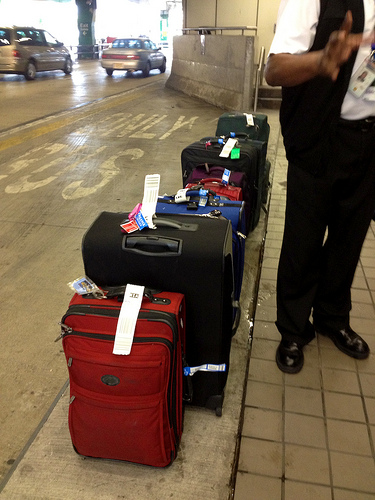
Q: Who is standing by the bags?
A: A man is standing there.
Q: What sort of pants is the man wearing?
A: They are black pants.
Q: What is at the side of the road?
A: Many pieces of luggage.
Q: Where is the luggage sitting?
A: The luggage is on the sidewalk.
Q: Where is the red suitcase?
A: It is on the sidewalk.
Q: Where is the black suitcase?
A: It on the sidewalk behind the red one.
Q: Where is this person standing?
A: He is in the foreground.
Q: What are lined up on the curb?
A: Luggage.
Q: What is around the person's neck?
A: Lanyard with ID.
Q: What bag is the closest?
A: Red bag.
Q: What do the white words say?
A: Only bus.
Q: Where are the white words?
A: On the pavement.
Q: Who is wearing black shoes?
A: A person.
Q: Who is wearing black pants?
A: A person.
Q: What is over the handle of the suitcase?
A: A label.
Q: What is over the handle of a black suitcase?
A: A label.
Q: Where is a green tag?
A: On black suitcase.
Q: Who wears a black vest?
A: A person.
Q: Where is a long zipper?
A: In the suicase.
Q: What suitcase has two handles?
A: Black suitcase.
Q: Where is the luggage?
A: On the gound.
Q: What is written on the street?
A: Bus Only.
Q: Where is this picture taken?
A: Near a public transportation area.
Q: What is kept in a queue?
A: Luggage bags.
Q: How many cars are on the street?
A: Two.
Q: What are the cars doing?
A: Moving away.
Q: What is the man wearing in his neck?
A: A badge.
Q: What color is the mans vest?
A: Black.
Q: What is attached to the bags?
A: Tags.